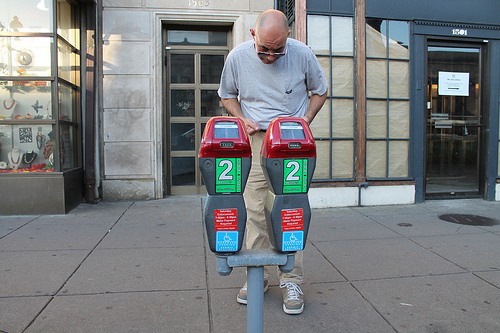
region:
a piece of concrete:
[315, 238, 463, 278]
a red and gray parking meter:
[263, 113, 319, 258]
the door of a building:
[425, 36, 486, 192]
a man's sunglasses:
[250, 40, 287, 57]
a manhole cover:
[440, 205, 495, 230]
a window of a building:
[361, 15, 387, 56]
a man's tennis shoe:
[276, 277, 306, 315]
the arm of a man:
[302, 53, 330, 115]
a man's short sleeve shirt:
[218, 35, 328, 135]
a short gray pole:
[240, 264, 270, 331]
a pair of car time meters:
[196, 115, 317, 330]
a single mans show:
[282, 278, 304, 314]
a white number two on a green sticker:
[283, 159, 305, 191]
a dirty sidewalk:
[2, 196, 497, 331]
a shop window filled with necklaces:
[0, 0, 90, 208]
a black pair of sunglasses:
[256, 46, 287, 60]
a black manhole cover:
[438, 212, 498, 227]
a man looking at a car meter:
[213, 6, 330, 314]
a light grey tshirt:
[218, 39, 325, 129]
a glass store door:
[425, 42, 490, 196]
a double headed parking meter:
[194, 113, 320, 331]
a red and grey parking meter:
[196, 112, 251, 255]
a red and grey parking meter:
[256, 115, 311, 251]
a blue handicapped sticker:
[214, 230, 239, 254]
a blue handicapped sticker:
[281, 231, 304, 253]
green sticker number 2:
[214, 156, 241, 193]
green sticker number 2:
[281, 159, 308, 192]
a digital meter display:
[213, 119, 237, 136]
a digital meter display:
[276, 119, 305, 138]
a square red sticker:
[279, 209, 304, 230]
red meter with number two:
[180, 105, 262, 263]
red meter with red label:
[257, 108, 312, 268]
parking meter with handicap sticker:
[260, 105, 321, 260]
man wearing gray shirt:
[220, 7, 312, 307]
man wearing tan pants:
[220, 2, 323, 314]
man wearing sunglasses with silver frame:
[212, 0, 324, 315]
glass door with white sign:
[427, 32, 487, 193]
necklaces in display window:
[3, 123, 43, 173]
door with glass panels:
[167, 43, 237, 197]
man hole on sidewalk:
[437, 203, 496, 243]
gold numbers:
[450, 27, 472, 37]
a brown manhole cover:
[436, 207, 496, 233]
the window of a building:
[0, 35, 48, 75]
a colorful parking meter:
[260, 108, 322, 248]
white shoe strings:
[280, 275, 302, 300]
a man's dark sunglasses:
[255, 35, 290, 60]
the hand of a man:
[238, 115, 258, 135]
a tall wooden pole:
[351, 0, 366, 181]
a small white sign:
[440, 71, 471, 93]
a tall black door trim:
[411, 25, 430, 194]